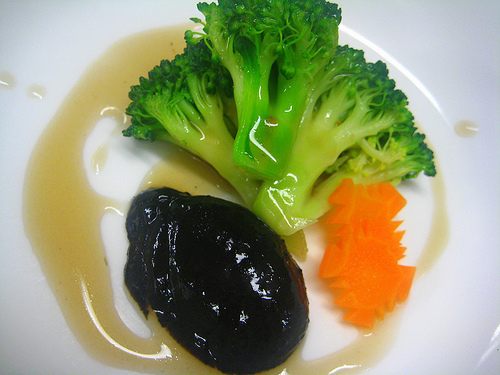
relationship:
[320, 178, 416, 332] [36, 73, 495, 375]
carrot on plate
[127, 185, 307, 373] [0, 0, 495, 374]
black shell on a plate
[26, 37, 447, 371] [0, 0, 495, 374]
liquid on plate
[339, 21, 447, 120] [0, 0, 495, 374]
light reflected on plate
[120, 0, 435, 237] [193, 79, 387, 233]
broccolli with sauce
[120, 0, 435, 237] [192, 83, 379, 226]
broccolli with sauce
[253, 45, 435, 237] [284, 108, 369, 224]
broccolli with sauce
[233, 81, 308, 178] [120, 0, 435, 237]
stem of broccolli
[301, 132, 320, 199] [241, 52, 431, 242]
stem of broccoli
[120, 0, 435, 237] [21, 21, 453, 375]
broccolli with liquid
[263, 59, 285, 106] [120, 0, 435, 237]
space between broccolli